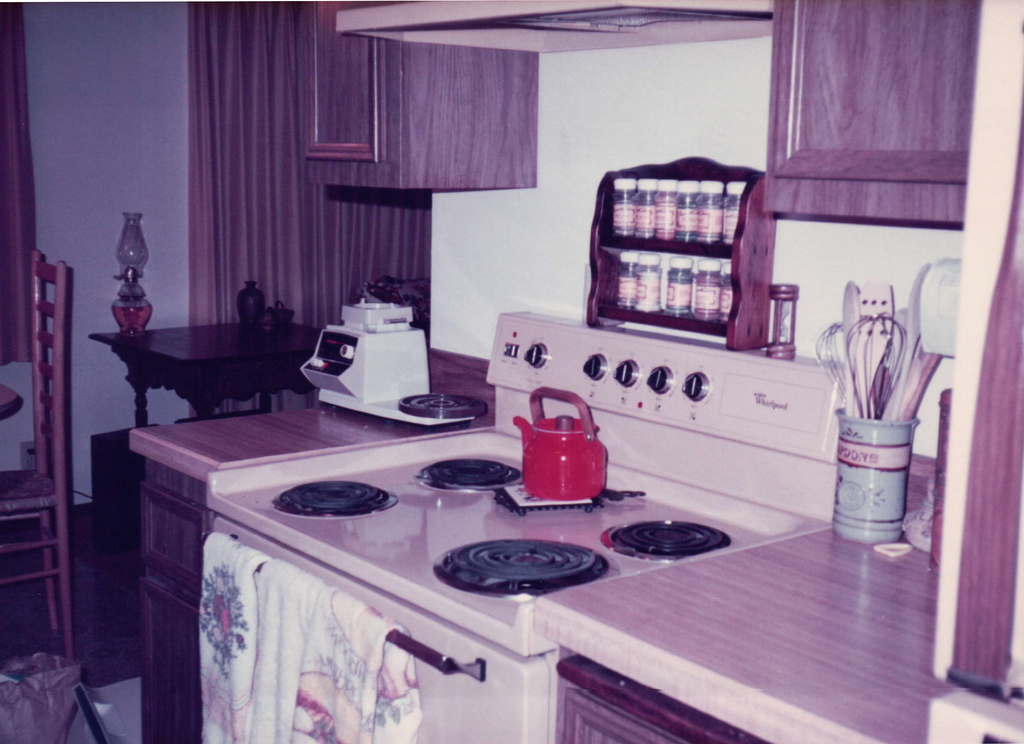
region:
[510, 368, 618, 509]
Pot on a stove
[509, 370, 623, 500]
Pot is on a stove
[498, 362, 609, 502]
Teapot on a stove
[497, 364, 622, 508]
Teapot is on a stove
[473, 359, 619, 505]
Red pot on a stove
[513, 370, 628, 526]
Red pot is on a stove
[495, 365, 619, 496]
Red teapot is on a stove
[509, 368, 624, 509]
Red teapot on a stove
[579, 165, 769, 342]
Spices on a rack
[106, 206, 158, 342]
oil lamp sitting on table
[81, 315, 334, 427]
wooden table in corner of room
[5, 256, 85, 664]
wooden dining table in front of chair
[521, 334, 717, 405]
whole bunch of knobs on stove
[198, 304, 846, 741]
cooking stove with electrical burners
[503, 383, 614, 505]
red tea kettle sitting on pot plate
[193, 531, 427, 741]
kitchen towels hanging on oven door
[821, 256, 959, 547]
ceramic container full of kitchen utensils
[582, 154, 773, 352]
wooden spice rack full of spices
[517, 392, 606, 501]
red teapot on the stove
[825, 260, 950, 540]
container with cooking utensils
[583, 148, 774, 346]
spice rack above the stove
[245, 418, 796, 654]
electric range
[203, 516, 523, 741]
oven door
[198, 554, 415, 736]
hand towels hanging from oven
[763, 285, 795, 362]
hourglass timer on top of stove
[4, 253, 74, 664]
wooden chair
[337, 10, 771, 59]
range hood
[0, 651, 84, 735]
brown paper bag on the floor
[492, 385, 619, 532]
red tea kettle on stove top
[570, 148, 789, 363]
wood spice rack on edge of stove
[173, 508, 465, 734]
towels hanging on stove handle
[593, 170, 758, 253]
row of spices on shelf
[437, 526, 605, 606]
electric burner on stove top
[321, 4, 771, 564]
tan vent over stove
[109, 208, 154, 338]
glass lamp with fuel in it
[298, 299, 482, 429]
white and black hot plate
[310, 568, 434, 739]
towel hanging on the voen door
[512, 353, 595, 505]
a red tea pot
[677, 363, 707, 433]
a black oven knob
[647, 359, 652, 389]
a black oven knob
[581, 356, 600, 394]
a black oven knob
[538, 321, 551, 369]
a black oven knob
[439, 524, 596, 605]
a black burner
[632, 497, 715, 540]
a black stove burner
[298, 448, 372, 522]
a black stove burner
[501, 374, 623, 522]
a kettle over a stove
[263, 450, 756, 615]
four burners on a stove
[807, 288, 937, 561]
utensils in a can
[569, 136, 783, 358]
spices on a rack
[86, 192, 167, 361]
an old lamp over a table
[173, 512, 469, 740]
kitchen towels on the stove handle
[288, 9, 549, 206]
the cabinet is brown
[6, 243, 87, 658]
the chair is wood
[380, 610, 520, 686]
the handle of an oven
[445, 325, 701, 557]
red kettle on stove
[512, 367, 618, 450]
handle of the kettle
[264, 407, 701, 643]
stove above the oven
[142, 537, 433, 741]
cloths on the oven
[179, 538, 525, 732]
oven under the stove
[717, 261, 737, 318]
A bottle of spices.